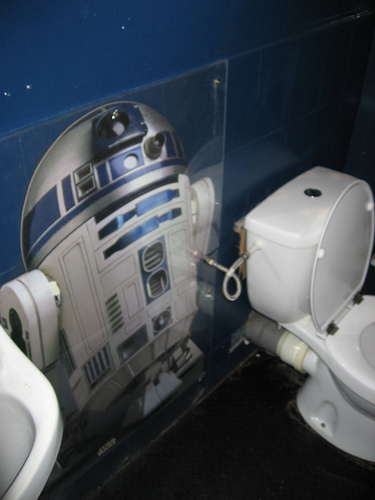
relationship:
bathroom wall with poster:
[2, 0, 373, 455] [1, 57, 231, 456]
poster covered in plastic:
[1, 57, 231, 456] [0, 2, 252, 398]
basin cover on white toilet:
[241, 164, 364, 251] [242, 165, 374, 463]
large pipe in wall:
[248, 313, 312, 367] [216, 295, 250, 328]